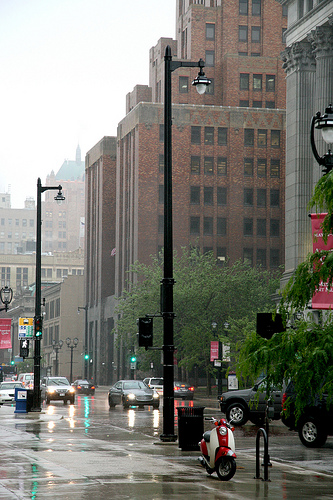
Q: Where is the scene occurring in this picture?
A: A big city.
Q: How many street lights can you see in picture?
A: 6.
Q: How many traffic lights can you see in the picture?
A: 5.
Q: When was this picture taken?
A: Mid afternoon.